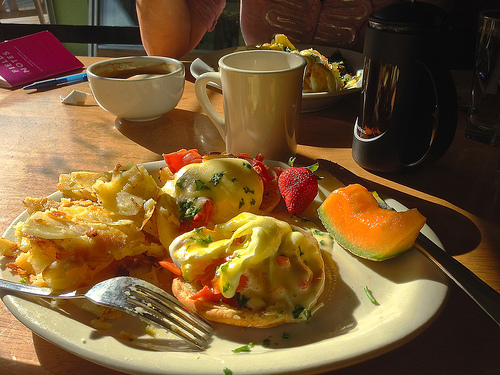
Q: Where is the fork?
A: In the plate.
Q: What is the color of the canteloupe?
A: Orange and green.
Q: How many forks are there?
A: 1.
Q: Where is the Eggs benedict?
A: Plate.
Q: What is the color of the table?
A: Brown.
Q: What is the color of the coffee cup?
A: White.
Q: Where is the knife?
A: In the plate.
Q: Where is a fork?
A: On a plate.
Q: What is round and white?
A: Plate.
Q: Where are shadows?
A: On the table.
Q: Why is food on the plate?
A: To be eaten.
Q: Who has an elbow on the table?
A: A person.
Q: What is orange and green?
A: Cantaloupe.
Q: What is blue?
A: A pen.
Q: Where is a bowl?
A: On the table.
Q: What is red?
A: A strawberry.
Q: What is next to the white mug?
A: A tall, silver and black cup.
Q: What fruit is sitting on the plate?
A: A slice of cantaloupe.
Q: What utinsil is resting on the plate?
A: A silver fork.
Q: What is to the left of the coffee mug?
A: Another cup of coffee.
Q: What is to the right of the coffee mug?
A: A shiny black coffee carafe.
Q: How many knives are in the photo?
A: One.